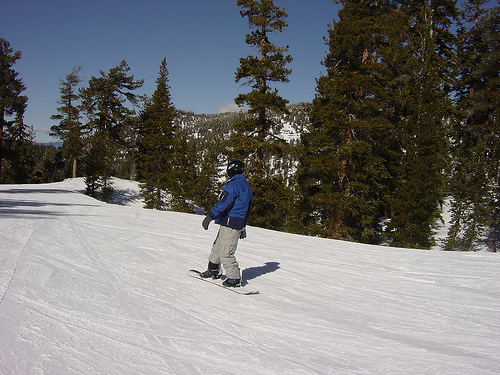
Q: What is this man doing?
A: He is snowboarding.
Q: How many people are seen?
A: Just 1 person.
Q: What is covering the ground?
A: Snow.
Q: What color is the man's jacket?
A: Blue and black.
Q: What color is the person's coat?
A: Blue.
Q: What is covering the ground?
A: Snow.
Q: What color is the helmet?
A: Black.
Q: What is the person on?
A: Snowboard.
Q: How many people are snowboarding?
A: One.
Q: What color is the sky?
A: Blue.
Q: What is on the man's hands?
A: Gloves.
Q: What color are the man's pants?
A: Grey.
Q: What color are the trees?
A: Green.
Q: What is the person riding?
A: Snowboard.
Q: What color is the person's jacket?
A: Blue.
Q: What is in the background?
A: Trees.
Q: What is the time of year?
A: Winter.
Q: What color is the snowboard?
A: White.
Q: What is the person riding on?
A: Snow.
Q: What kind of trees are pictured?
A: Pine.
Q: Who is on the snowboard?
A: The snowboarder.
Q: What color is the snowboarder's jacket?
A: Blue.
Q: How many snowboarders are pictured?
A: One.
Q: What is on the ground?
A: Snow.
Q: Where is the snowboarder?
A: On a hill.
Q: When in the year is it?
A: Wintertime.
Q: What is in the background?
A: Trees and a mountain.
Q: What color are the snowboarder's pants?
A: Grey.